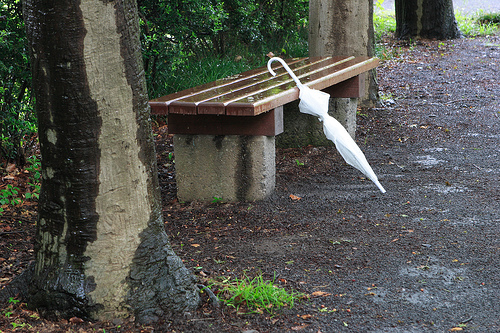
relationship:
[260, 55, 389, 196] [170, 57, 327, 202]
umbrella leaning on bench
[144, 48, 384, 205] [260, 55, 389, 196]
bench with umbrella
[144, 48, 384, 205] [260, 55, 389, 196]
bench with a umbrella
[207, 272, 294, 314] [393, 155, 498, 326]
grass on ground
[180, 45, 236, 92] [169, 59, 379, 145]
grass growing behind bench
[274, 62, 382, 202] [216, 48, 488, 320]
umbrella on ground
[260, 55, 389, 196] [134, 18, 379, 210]
umbrella on bench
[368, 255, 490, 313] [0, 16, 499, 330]
spot on ground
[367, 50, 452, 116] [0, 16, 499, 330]
leaves on ground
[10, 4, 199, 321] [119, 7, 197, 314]
tree trunk with black mark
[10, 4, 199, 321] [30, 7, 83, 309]
tree trunk with black mark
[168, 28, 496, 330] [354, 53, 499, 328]
ground covered with soil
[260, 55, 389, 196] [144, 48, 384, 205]
umbrella leaning on bench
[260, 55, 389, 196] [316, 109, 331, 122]
umbrella closed with strap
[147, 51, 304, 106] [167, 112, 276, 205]
board above base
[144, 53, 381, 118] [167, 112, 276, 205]
board above base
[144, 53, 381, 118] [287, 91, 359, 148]
board above cement support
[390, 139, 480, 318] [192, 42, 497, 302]
puddles on ground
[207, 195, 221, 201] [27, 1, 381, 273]
growth between trunks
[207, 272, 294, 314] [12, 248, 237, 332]
grass at tree base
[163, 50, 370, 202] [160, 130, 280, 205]
bench with base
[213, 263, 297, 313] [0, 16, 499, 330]
grass on ground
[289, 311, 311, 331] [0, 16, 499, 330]
leaves on ground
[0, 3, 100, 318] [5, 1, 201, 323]
wet spot on trunk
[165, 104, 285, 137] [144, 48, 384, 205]
piece on bench